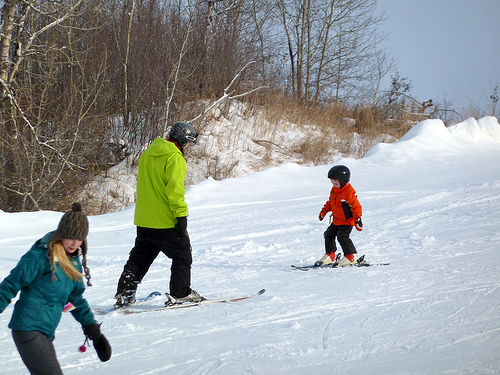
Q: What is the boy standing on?
A: Skis.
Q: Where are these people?
A: Ski slope.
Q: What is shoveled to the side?
A: Snow.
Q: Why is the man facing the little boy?
A: Teaching him.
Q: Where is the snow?
A: On the ground.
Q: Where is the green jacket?
A: On the man.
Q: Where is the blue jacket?
A: On the girl.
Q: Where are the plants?
A: In the ground.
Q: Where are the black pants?
A: On the skiers.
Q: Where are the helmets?
A: On the skiers.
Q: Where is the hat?
A: On the girl.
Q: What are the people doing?
A: Skiing.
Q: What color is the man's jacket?
A: Chartreuse.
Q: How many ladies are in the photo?
A: One.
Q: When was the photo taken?
A: Daytime.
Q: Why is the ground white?
A: It snowed.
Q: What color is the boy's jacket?
A: Red.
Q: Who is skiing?
A: A family.